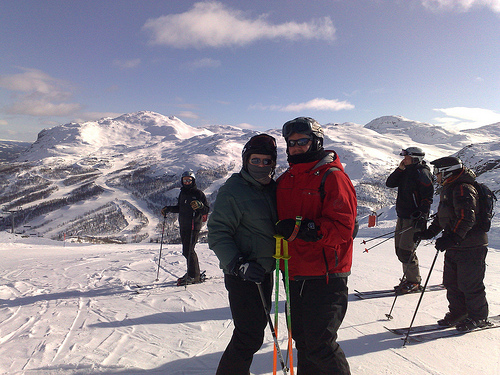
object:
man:
[275, 116, 357, 375]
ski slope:
[4, 235, 499, 375]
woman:
[207, 133, 278, 374]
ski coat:
[275, 150, 358, 281]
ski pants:
[283, 277, 351, 375]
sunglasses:
[287, 138, 311, 147]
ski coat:
[207, 170, 277, 275]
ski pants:
[216, 274, 273, 374]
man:
[413, 156, 489, 331]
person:
[385, 147, 436, 293]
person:
[161, 171, 209, 285]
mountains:
[1, 109, 500, 241]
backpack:
[460, 179, 497, 233]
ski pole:
[402, 249, 440, 347]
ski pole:
[384, 237, 422, 320]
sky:
[0, 1, 499, 144]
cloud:
[139, 1, 339, 53]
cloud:
[280, 96, 357, 111]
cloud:
[4, 64, 81, 118]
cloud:
[420, 0, 499, 16]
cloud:
[112, 56, 143, 70]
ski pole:
[283, 238, 294, 374]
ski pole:
[272, 233, 281, 374]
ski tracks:
[50, 295, 87, 374]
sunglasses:
[249, 157, 272, 165]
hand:
[400, 159, 406, 170]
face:
[403, 154, 411, 166]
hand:
[275, 220, 302, 240]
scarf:
[241, 162, 272, 187]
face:
[249, 149, 272, 179]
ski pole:
[155, 213, 167, 282]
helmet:
[282, 116, 324, 147]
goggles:
[282, 120, 311, 135]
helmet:
[401, 147, 427, 162]